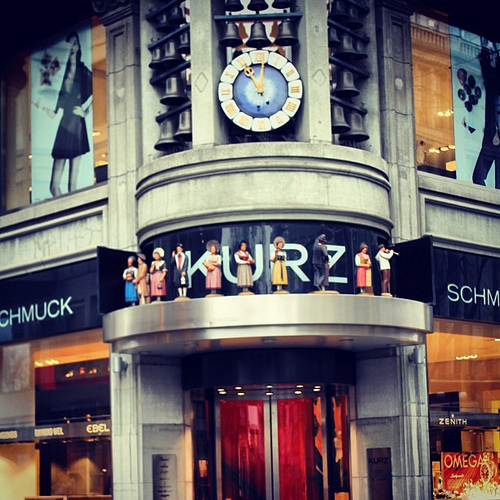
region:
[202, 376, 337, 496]
The front door to the store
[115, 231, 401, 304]
The figurines on the store entrance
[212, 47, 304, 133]
The clock on top of the building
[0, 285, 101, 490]
The store window of the building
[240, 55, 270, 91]
The hands on the clock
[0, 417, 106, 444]
The name brand logo's in the window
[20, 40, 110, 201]
A poster of a woman in the window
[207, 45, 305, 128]
The clock has roman numerals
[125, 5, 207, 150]
The bells on top of the building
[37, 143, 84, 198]
The legs of the woman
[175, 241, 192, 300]
A figurine on top of a awing wearing a black coat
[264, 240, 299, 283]
A figurine on top of a awing wearing a yellow dress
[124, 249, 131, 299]
A figurine on top of a awing wearing a blue dress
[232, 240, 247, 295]
A figurine on top of a awing wearing grey dress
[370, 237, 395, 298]
A figurine on top of a awing wearing a fedora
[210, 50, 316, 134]
A clock on the building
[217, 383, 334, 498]
Glass door entryway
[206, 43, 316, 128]
Clock on the side of a building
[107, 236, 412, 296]
Toys on top of a building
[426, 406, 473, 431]
Zenith sign in the building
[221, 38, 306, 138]
Clock on the side of a building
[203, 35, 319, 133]
Clock on the side of a building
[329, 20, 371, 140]
Bells on the building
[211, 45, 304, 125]
Clock on the side of a building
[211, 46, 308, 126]
Clock on the side of a building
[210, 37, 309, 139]
Clock on the side of a building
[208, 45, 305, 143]
Clock on the side of a building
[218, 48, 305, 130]
The clock is gold and blue.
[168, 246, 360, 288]
The store is Kurz.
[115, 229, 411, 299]
There are little statues on top of the door.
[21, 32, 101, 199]
The advertisement has a woman in a black dress.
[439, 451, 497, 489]
Omega perfume is in the window.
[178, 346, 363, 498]
The door is revolving.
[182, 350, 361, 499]
The door is glass door.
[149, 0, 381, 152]
There are lots of bells on top of the building.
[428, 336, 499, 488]
The lights are on inside.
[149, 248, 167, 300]
This statue is wearing a white hat.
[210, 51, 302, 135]
small clock on building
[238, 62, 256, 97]
small golden hand of clock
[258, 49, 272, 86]
large golden hand of clock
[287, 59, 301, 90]
numbers on side of clock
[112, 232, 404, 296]
sign on front of building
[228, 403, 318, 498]
red curtains on entrance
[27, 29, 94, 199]
large pictures on window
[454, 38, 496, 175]
large picture on window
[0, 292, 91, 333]
white writing on side of wall